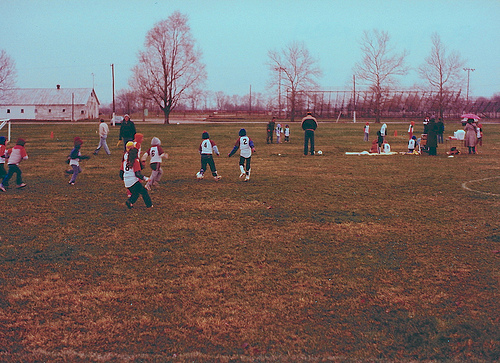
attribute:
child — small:
[192, 128, 223, 180]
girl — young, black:
[108, 126, 158, 211]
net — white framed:
[1, 111, 17, 171]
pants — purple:
[71, 166, 79, 180]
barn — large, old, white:
[2, 80, 104, 122]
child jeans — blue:
[0, 129, 44, 195]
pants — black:
[301, 131, 317, 154]